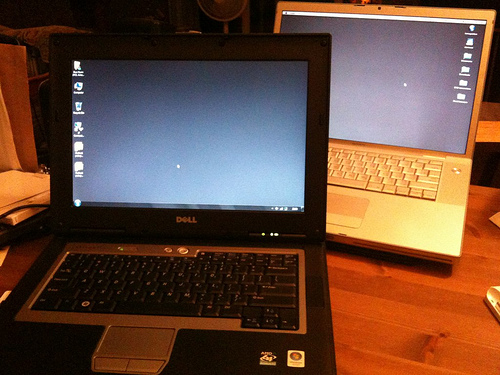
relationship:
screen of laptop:
[66, 53, 309, 213] [38, 66, 336, 350]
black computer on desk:
[1, 32, 337, 375] [0, 159, 497, 363]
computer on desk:
[269, 0, 493, 266] [0, 159, 497, 363]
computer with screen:
[269, 0, 493, 266] [281, 10, 486, 152]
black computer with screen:
[1, 32, 337, 375] [66, 53, 309, 213]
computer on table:
[269, 0, 493, 266] [1, 166, 498, 372]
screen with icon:
[66, 53, 309, 213] [69, 56, 84, 75]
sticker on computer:
[286, 343, 304, 369] [269, 0, 493, 266]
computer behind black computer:
[273, 5, 493, 266] [1, 32, 337, 375]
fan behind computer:
[202, 1, 262, 32] [269, 0, 493, 266]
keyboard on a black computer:
[31, 245, 304, 331] [1, 32, 337, 375]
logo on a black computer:
[174, 216, 199, 225] [1, 32, 337, 375]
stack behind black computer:
[0, 169, 51, 225] [1, 32, 338, 373]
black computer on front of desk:
[1, 32, 337, 375] [2, 101, 499, 373]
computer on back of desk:
[269, 0, 493, 266] [361, 275, 442, 361]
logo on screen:
[174, 216, 199, 225] [66, 53, 309, 213]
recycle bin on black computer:
[73, 99, 88, 116] [1, 32, 337, 375]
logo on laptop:
[174, 216, 199, 225] [35, 27, 340, 372]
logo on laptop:
[152, 203, 224, 233] [35, 27, 340, 372]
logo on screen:
[73, 160, 83, 179] [88, 72, 284, 217]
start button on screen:
[65, 188, 90, 210] [63, 192, 85, 212]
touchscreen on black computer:
[98, 322, 181, 362] [1, 32, 337, 375]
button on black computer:
[177, 246, 189, 256] [1, 32, 337, 375]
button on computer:
[450, 166, 461, 175] [269, 0, 493, 266]